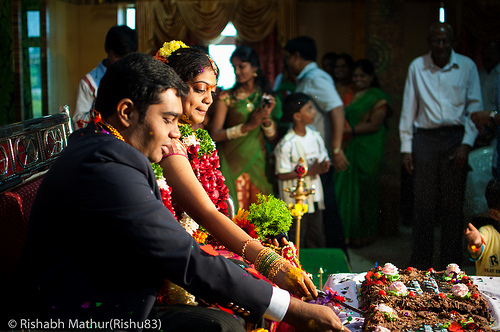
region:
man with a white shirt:
[378, 15, 479, 263]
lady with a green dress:
[218, 22, 276, 191]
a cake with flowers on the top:
[356, 254, 494, 321]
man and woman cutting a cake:
[31, 45, 486, 325]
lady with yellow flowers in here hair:
[160, 35, 223, 115]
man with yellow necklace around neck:
[88, 41, 185, 167]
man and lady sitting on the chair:
[15, 45, 235, 295]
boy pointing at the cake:
[417, 160, 492, 325]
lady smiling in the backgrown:
[334, 53, 396, 128]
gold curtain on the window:
[112, 16, 322, 93]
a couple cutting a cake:
[77, 13, 493, 325]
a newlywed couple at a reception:
[53, 32, 473, 327]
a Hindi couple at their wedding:
[62, 30, 396, 330]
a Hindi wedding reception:
[23, 5, 496, 309]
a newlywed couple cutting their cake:
[69, 19, 481, 329]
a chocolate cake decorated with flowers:
[357, 258, 497, 330]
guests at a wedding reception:
[226, 25, 495, 225]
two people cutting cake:
[88, 18, 438, 327]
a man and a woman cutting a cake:
[83, 19, 469, 330]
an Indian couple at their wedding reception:
[74, 23, 478, 330]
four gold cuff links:
[224, 294, 252, 316]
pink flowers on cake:
[385, 261, 407, 295]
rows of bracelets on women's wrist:
[254, 248, 286, 277]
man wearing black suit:
[61, 64, 181, 274]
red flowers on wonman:
[182, 145, 223, 202]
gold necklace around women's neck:
[228, 92, 261, 114]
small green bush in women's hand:
[250, 201, 291, 238]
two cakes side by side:
[358, 262, 494, 331]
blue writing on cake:
[405, 279, 440, 294]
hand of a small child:
[459, 220, 498, 257]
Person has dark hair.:
[111, 50, 163, 120]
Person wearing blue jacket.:
[88, 135, 175, 240]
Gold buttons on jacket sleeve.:
[225, 296, 248, 326]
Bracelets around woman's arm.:
[237, 226, 292, 282]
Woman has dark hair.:
[178, 44, 211, 94]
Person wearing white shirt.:
[277, 128, 331, 190]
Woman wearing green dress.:
[230, 102, 277, 201]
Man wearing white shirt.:
[410, 52, 492, 119]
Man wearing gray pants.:
[408, 130, 483, 260]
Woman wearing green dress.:
[351, 92, 371, 239]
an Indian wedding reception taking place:
[5, 5, 498, 327]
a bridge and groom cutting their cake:
[2, 5, 494, 327]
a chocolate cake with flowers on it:
[361, 259, 493, 330]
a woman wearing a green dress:
[215, 38, 277, 188]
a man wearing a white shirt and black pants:
[391, 13, 475, 258]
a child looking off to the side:
[276, 88, 331, 241]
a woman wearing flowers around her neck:
[161, 38, 318, 294]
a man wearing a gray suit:
[28, 48, 193, 328]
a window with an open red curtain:
[134, 4, 279, 83]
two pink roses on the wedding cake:
[380, 262, 410, 299]